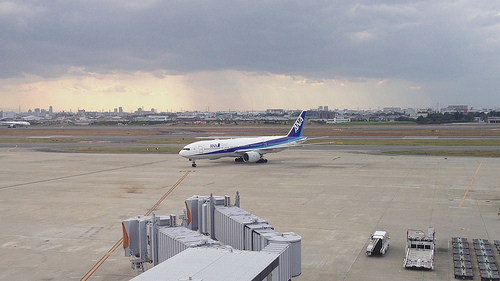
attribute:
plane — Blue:
[168, 112, 319, 169]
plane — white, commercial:
[174, 105, 312, 168]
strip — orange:
[77, 163, 198, 280]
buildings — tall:
[47, 103, 55, 116]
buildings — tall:
[38, 105, 45, 116]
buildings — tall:
[31, 105, 41, 115]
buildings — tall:
[116, 103, 125, 114]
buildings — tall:
[111, 103, 119, 114]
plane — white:
[173, 109, 316, 172]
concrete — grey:
[323, 163, 428, 217]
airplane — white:
[161, 92, 301, 183]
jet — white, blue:
[168, 102, 322, 163]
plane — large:
[187, 94, 316, 184]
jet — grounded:
[177, 105, 328, 172]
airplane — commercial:
[177, 107, 336, 167]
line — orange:
[75, 148, 205, 278]